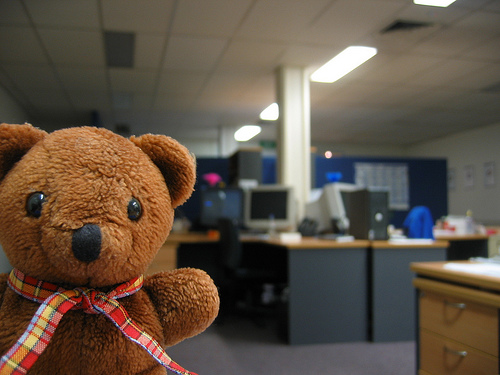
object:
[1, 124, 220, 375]
teddy bear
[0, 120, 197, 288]
head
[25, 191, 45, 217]
eye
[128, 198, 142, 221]
eye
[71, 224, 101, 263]
nose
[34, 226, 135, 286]
mouth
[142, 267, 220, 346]
arm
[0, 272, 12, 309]
arm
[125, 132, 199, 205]
ear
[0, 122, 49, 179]
ear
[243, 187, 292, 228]
monitor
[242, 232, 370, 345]
desk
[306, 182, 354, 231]
monitor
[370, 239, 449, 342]
desk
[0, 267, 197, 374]
scarf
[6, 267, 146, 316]
neck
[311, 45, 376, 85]
light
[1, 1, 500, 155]
ceiling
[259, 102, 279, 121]
light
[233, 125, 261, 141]
light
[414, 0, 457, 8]
light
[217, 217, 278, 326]
chair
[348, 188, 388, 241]
computer tower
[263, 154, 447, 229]
cubicle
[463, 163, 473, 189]
paper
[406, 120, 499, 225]
wall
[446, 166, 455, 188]
paper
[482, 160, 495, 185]
paper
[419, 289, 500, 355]
drawer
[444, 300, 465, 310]
handle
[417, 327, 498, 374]
drawer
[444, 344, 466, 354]
handle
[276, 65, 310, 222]
pole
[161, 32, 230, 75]
ceiling tile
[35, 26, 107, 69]
ceiling tile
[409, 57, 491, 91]
ceiling tile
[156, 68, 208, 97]
ceiling tile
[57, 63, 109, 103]
ceiling tile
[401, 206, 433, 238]
jacket